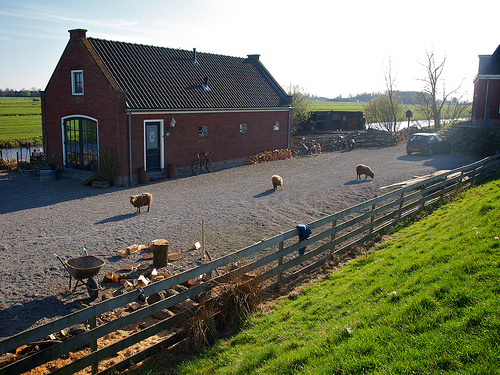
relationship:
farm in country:
[122, 150, 352, 245] [2, 88, 497, 370]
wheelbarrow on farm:
[53, 248, 106, 300] [10, 24, 499, 374]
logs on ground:
[149, 235, 174, 269] [1, 97, 498, 373]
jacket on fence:
[296, 222, 310, 256] [112, 198, 435, 330]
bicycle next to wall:
[188, 148, 218, 177] [129, 107, 292, 179]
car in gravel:
[404, 131, 451, 156] [186, 146, 424, 244]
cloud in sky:
[121, 3, 497, 108] [15, 106, 48, 129]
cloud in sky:
[121, 3, 497, 108] [2, 2, 493, 104]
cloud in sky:
[121, 3, 497, 108] [7, 0, 155, 44]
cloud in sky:
[121, 3, 497, 108] [91, 4, 496, 98]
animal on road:
[271, 175, 283, 191] [8, 137, 452, 372]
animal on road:
[356, 164, 375, 179] [5, 132, 380, 339]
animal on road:
[129, 193, 152, 213] [5, 132, 380, 339]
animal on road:
[271, 175, 283, 191] [5, 132, 380, 339]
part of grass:
[233, 346, 297, 360] [126, 174, 498, 374]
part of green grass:
[265, 312, 321, 352] [183, 183, 499, 373]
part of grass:
[292, 318, 384, 371] [179, 178, 498, 373]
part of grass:
[454, 186, 493, 241] [179, 178, 498, 373]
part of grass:
[399, 238, 469, 276] [179, 178, 498, 373]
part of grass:
[387, 297, 481, 352] [179, 178, 498, 373]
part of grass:
[345, 288, 402, 333] [179, 178, 498, 373]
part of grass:
[386, 246, 418, 278] [377, 229, 462, 304]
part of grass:
[424, 297, 470, 347] [339, 239, 499, 374]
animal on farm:
[354, 163, 374, 179] [10, 24, 499, 374]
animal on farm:
[270, 174, 283, 189] [10, 24, 499, 374]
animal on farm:
[127, 192, 154, 211] [10, 24, 499, 374]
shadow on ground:
[82, 208, 149, 238] [1, 97, 498, 373]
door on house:
[142, 117, 167, 172] [38, 28, 292, 188]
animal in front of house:
[129, 193, 152, 213] [38, 28, 292, 188]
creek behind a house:
[2, 114, 467, 165] [38, 28, 292, 188]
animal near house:
[129, 193, 152, 213] [38, 28, 292, 188]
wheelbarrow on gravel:
[51, 243, 120, 305] [2, 142, 486, 353]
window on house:
[68, 67, 85, 93] [38, 28, 292, 188]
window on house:
[198, 125, 209, 137] [38, 28, 292, 188]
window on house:
[239, 124, 249, 136] [38, 28, 292, 188]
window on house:
[273, 122, 281, 130] [38, 28, 292, 188]